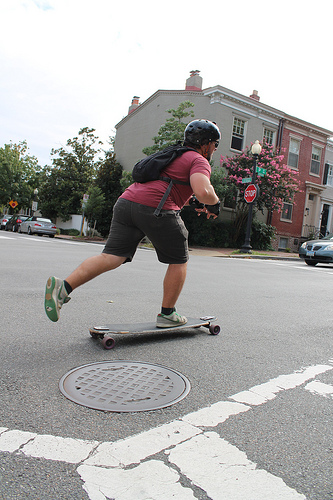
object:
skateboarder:
[44, 118, 222, 328]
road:
[0, 228, 332, 499]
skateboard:
[89, 314, 221, 349]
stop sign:
[243, 183, 257, 205]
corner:
[139, 214, 326, 260]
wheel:
[100, 335, 117, 351]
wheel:
[209, 323, 221, 337]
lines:
[0, 357, 332, 498]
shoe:
[44, 275, 71, 323]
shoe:
[155, 310, 188, 327]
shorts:
[102, 198, 189, 265]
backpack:
[131, 141, 206, 216]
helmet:
[182, 117, 222, 149]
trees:
[0, 138, 45, 215]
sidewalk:
[23, 223, 331, 260]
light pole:
[239, 158, 258, 253]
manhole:
[58, 358, 191, 413]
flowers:
[219, 135, 305, 213]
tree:
[221, 137, 304, 248]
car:
[297, 235, 332, 266]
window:
[230, 116, 247, 154]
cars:
[21, 214, 58, 238]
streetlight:
[237, 138, 262, 253]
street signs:
[255, 164, 267, 178]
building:
[114, 69, 332, 251]